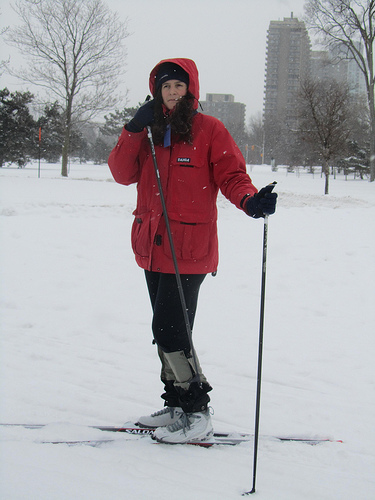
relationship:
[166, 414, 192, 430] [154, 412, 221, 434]
laces on shoe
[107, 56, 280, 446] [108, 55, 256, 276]
lady wearing coat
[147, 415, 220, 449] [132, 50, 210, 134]
ski boot on lady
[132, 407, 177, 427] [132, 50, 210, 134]
ski boot on lady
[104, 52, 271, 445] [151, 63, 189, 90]
lady wearing cap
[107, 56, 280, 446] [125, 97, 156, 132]
lady wearing gloves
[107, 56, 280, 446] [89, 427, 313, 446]
lady with skis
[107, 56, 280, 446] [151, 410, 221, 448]
lady with ski boot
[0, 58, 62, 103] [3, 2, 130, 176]
branch on tree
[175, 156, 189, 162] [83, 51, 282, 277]
label on coat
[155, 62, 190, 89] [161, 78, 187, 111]
hat on head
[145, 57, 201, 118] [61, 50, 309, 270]
hood on coat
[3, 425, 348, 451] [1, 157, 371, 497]
skis on snows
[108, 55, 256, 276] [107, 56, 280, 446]
coat on lady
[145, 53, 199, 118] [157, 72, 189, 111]
hood worn on head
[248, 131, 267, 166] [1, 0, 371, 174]
traffic light in background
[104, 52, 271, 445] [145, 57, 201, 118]
lady wearing a hood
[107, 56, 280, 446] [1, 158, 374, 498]
lady standing in snow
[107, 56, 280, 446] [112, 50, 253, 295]
lady with coat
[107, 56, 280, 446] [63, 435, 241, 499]
lady standing in snow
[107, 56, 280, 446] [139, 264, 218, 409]
lady with black pants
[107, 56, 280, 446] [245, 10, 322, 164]
lady with buildings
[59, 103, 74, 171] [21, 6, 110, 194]
trunk on tree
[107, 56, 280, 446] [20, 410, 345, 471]
lady on skiis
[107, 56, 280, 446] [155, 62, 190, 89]
lady wears hat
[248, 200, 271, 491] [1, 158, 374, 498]
ski pole in snow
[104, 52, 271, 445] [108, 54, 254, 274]
lady wearing a ski jacket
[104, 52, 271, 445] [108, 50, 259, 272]
lady wearing a ski jacket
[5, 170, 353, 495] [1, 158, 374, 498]
field with snow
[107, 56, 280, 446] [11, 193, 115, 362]
lady standing in snow